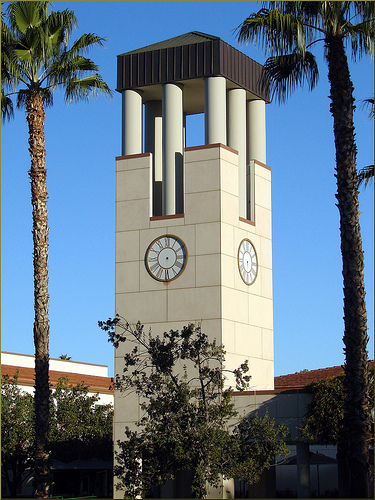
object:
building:
[7, 350, 369, 497]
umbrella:
[305, 449, 335, 466]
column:
[163, 84, 185, 215]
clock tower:
[111, 31, 280, 498]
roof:
[109, 27, 266, 92]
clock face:
[145, 233, 187, 282]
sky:
[72, 0, 271, 64]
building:
[0, 352, 120, 404]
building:
[221, 366, 372, 445]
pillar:
[297, 445, 318, 498]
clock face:
[146, 236, 182, 282]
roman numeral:
[162, 234, 172, 246]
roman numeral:
[171, 258, 182, 268]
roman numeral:
[146, 256, 158, 265]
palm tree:
[248, 5, 370, 101]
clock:
[134, 221, 209, 317]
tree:
[96, 304, 278, 490]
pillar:
[144, 76, 215, 263]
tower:
[100, 23, 268, 369]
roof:
[105, 16, 297, 112]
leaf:
[235, 19, 335, 154]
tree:
[245, 0, 362, 203]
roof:
[89, 8, 281, 125]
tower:
[101, 16, 283, 449]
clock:
[135, 214, 190, 287]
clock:
[143, 229, 205, 288]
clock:
[234, 231, 264, 300]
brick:
[164, 282, 223, 318]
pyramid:
[106, 25, 279, 106]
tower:
[112, 29, 284, 389]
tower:
[109, 11, 276, 445]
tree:
[5, 0, 123, 491]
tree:
[101, 315, 283, 498]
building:
[100, 35, 297, 442]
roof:
[98, 12, 302, 121]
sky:
[54, 117, 99, 229]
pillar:
[138, 86, 193, 217]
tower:
[90, 12, 291, 359]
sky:
[29, 107, 106, 236]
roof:
[281, 356, 358, 396]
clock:
[139, 237, 192, 285]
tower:
[102, 16, 282, 328]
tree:
[238, 1, 363, 291]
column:
[148, 77, 206, 218]